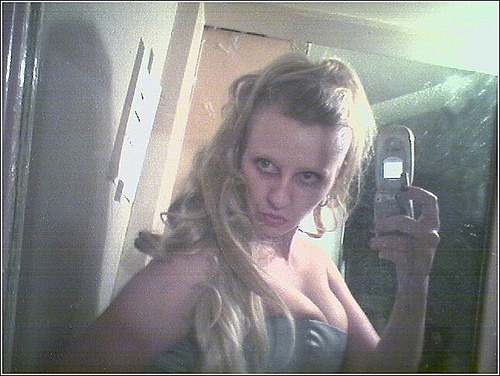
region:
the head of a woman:
[231, 49, 383, 241]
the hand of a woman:
[363, 178, 449, 285]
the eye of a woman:
[293, 164, 322, 189]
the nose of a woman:
[263, 165, 297, 215]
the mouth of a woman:
[251, 204, 296, 227]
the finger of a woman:
[398, 180, 443, 224]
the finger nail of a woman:
[395, 180, 411, 193]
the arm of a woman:
[41, 242, 216, 374]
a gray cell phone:
[367, 119, 423, 264]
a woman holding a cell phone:
[31, 40, 436, 375]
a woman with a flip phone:
[4, 7, 496, 369]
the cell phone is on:
[371, 122, 419, 274]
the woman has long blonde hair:
[136, 56, 377, 374]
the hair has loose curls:
[128, 61, 315, 361]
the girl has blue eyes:
[253, 142, 328, 201]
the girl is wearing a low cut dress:
[183, 64, 370, 374]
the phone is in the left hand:
[372, 115, 447, 340]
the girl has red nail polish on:
[366, 173, 430, 269]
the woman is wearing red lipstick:
[255, 207, 296, 236]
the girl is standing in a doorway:
[28, 11, 493, 361]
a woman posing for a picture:
[51, 54, 463, 374]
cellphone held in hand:
[365, 126, 445, 302]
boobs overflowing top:
[252, 283, 362, 373]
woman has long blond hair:
[161, 47, 368, 370]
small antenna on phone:
[395, 170, 417, 204]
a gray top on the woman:
[161, 312, 368, 374]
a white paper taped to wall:
[103, 32, 157, 225]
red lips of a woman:
[255, 203, 292, 233]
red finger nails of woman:
[360, 178, 421, 270]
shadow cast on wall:
[33, 18, 130, 373]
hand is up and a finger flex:
[370, 185, 440, 282]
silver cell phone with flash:
[374, 115, 414, 212]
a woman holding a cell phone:
[368, 116, 455, 361]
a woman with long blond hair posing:
[155, 62, 352, 365]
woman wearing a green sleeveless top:
[158, 322, 352, 374]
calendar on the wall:
[105, 30, 171, 216]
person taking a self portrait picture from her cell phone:
[61, 50, 499, 365]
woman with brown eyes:
[237, 120, 339, 196]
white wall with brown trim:
[13, 2, 168, 237]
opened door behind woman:
[173, 47, 496, 359]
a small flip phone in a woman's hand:
[366, 125, 441, 272]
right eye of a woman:
[252, 155, 282, 176]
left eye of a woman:
[293, 160, 325, 189]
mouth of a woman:
[256, 209, 290, 228]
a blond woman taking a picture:
[61, 56, 437, 374]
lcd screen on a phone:
[380, 157, 404, 182]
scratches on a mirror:
[438, 75, 496, 260]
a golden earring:
[320, 195, 332, 210]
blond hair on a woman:
[199, 257, 257, 363]